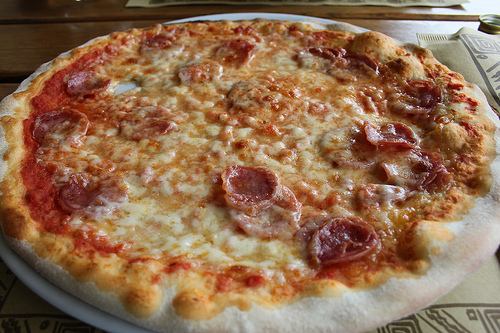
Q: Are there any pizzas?
A: Yes, there is a pizza.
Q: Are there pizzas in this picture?
A: Yes, there is a pizza.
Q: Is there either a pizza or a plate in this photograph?
A: Yes, there is a pizza.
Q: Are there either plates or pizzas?
A: Yes, there is a pizza.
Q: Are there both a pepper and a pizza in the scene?
A: No, there is a pizza but no peppers.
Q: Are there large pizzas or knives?
A: Yes, there is a large pizza.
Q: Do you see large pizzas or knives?
A: Yes, there is a large pizza.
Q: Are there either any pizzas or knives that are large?
A: Yes, the pizza is large.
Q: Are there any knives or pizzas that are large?
A: Yes, the pizza is large.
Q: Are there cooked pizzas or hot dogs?
A: Yes, there is a cooked pizza.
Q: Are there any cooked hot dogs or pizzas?
A: Yes, there is a cooked pizza.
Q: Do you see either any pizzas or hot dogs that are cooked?
A: Yes, the pizza is cooked.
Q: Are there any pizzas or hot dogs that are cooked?
A: Yes, the pizza is cooked.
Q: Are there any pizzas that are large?
A: Yes, there is a large pizza.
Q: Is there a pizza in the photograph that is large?
A: Yes, there is a large pizza.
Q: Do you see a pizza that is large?
A: Yes, there is a pizza that is large.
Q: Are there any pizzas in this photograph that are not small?
A: Yes, there is a large pizza.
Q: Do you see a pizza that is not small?
A: Yes, there is a large pizza.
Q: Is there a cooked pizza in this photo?
A: Yes, there is a cooked pizza.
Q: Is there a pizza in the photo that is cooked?
A: Yes, there is a pizza that is cooked.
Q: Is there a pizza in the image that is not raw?
A: Yes, there is a cooked pizza.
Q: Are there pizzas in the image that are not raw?
A: Yes, there is a cooked pizza.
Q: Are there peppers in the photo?
A: No, there are no peppers.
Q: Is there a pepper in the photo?
A: No, there are no peppers.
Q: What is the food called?
A: The food is a pizza.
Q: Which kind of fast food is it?
A: The food is a pizza.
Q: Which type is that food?
A: This is a pizza.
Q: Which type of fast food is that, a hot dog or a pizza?
A: This is a pizza.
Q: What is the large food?
A: The food is a pizza.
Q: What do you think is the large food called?
A: The food is a pizza.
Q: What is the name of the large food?
A: The food is a pizza.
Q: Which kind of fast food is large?
A: The fast food is a pizza.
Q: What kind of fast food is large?
A: The fast food is a pizza.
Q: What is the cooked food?
A: The food is a pizza.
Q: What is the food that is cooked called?
A: The food is a pizza.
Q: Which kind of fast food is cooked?
A: The fast food is a pizza.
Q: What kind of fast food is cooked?
A: The fast food is a pizza.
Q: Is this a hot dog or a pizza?
A: This is a pizza.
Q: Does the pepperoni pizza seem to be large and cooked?
A: Yes, the pizza is large and cooked.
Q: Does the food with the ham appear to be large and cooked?
A: Yes, the pizza is large and cooked.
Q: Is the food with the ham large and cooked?
A: Yes, the pizza is large and cooked.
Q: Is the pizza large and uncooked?
A: No, the pizza is large but cooked.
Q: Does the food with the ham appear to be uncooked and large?
A: No, the pizza is large but cooked.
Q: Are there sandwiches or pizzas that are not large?
A: No, there is a pizza but it is large.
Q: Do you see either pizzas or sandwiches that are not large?
A: No, there is a pizza but it is large.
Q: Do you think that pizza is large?
A: Yes, the pizza is large.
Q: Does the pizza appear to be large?
A: Yes, the pizza is large.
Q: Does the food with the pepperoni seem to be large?
A: Yes, the pizza is large.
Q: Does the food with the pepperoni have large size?
A: Yes, the pizza is large.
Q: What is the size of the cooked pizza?
A: The pizza is large.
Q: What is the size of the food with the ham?
A: The pizza is large.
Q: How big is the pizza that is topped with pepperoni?
A: The pizza is large.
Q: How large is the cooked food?
A: The pizza is large.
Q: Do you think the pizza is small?
A: No, the pizza is large.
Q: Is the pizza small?
A: No, the pizza is large.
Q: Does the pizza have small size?
A: No, the pizza is large.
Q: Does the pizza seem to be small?
A: No, the pizza is large.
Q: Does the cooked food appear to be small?
A: No, the pizza is large.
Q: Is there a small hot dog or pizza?
A: No, there is a pizza but it is large.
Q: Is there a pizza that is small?
A: No, there is a pizza but it is large.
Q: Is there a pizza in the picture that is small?
A: No, there is a pizza but it is large.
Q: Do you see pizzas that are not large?
A: No, there is a pizza but it is large.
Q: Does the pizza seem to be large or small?
A: The pizza is large.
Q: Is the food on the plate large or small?
A: The pizza is large.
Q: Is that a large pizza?
A: Yes, that is a large pizza.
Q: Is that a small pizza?
A: No, that is a large pizza.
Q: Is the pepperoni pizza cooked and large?
A: Yes, the pizza is cooked and large.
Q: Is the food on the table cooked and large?
A: Yes, the pizza is cooked and large.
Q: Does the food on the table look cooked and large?
A: Yes, the pizza is cooked and large.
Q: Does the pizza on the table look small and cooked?
A: No, the pizza is cooked but large.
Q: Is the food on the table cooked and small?
A: No, the pizza is cooked but large.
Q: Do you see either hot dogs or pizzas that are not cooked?
A: No, there is a pizza but it is cooked.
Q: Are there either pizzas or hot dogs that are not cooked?
A: No, there is a pizza but it is cooked.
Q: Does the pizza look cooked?
A: Yes, the pizza is cooked.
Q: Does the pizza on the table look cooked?
A: Yes, the pizza is cooked.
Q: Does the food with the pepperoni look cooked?
A: Yes, the pizza is cooked.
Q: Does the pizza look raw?
A: No, the pizza is cooked.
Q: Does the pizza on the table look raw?
A: No, the pizza is cooked.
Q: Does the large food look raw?
A: No, the pizza is cooked.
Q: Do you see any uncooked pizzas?
A: No, there is a pizza but it is cooked.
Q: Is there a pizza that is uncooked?
A: No, there is a pizza but it is cooked.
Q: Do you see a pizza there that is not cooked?
A: No, there is a pizza but it is cooked.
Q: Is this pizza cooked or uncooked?
A: The pizza is cooked.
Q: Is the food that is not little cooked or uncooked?
A: The pizza is cooked.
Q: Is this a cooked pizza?
A: Yes, this is a cooked pizza.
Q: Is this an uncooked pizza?
A: No, this is a cooked pizza.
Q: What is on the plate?
A: The pizza is on the plate.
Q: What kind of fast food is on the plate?
A: The food is a pizza.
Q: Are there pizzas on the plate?
A: Yes, there is a pizza on the plate.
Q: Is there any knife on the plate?
A: No, there is a pizza on the plate.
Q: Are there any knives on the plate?
A: No, there is a pizza on the plate.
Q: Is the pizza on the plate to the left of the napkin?
A: Yes, the pizza is on the plate.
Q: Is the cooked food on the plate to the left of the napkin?
A: Yes, the pizza is on the plate.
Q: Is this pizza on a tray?
A: No, the pizza is on the plate.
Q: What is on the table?
A: The pizza is on the table.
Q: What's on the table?
A: The pizza is on the table.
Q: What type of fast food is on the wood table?
A: The food is a pizza.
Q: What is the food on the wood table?
A: The food is a pizza.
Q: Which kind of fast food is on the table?
A: The food is a pizza.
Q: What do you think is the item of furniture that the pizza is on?
A: The piece of furniture is a table.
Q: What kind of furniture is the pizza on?
A: The pizza is on the table.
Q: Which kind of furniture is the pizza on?
A: The pizza is on the table.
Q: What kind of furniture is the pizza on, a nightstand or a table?
A: The pizza is on a table.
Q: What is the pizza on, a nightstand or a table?
A: The pizza is on a table.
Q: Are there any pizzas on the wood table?
A: Yes, there is a pizza on the table.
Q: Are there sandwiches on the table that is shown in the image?
A: No, there is a pizza on the table.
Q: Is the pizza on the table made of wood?
A: Yes, the pizza is on the table.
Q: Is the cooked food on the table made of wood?
A: Yes, the pizza is on the table.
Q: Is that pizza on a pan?
A: No, the pizza is on the table.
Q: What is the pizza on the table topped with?
A: The pizza is topped with pepperoni.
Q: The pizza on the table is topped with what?
A: The pizza is topped with pepperoni.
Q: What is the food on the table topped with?
A: The pizza is topped with pepperoni.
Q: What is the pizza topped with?
A: The pizza is topped with pepperoni.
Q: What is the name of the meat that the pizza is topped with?
A: The meat is pepperoni.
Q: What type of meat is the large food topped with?
A: The pizza is topped with pepperoni.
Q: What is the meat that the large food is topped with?
A: The meat is pepperoni.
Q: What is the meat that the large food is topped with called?
A: The meat is pepperoni.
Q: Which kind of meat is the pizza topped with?
A: The pizza is topped with pepperoni.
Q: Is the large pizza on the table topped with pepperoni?
A: Yes, the pizza is topped with pepperoni.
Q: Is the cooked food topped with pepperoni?
A: Yes, the pizza is topped with pepperoni.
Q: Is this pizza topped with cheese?
A: No, the pizza is topped with pepperoni.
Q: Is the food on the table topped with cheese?
A: No, the pizza is topped with pepperoni.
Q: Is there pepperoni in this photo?
A: Yes, there is pepperoni.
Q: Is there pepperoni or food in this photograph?
A: Yes, there is pepperoni.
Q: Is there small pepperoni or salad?
A: Yes, there is small pepperoni.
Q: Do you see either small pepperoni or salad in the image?
A: Yes, there is small pepperoni.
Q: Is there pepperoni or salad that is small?
A: Yes, the pepperoni is small.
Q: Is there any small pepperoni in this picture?
A: Yes, there is small pepperoni.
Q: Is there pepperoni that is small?
A: Yes, there is pepperoni that is small.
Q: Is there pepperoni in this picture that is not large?
A: Yes, there is small pepperoni.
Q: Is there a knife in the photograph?
A: No, there are no knives.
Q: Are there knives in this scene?
A: No, there are no knives.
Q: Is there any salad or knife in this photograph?
A: No, there are no knives or salad.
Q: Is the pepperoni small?
A: Yes, the pepperoni is small.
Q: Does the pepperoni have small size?
A: Yes, the pepperoni is small.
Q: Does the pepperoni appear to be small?
A: Yes, the pepperoni is small.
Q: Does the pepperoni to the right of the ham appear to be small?
A: Yes, the pepperoni is small.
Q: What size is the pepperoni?
A: The pepperoni is small.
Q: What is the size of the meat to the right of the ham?
A: The pepperoni is small.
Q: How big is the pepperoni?
A: The pepperoni is small.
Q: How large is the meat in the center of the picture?
A: The pepperoni is small.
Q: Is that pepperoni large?
A: No, the pepperoni is small.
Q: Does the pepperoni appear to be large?
A: No, the pepperoni is small.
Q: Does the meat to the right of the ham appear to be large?
A: No, the pepperoni is small.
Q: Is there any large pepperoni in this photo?
A: No, there is pepperoni but it is small.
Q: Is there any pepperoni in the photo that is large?
A: No, there is pepperoni but it is small.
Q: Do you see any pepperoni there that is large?
A: No, there is pepperoni but it is small.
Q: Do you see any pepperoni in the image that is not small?
A: No, there is pepperoni but it is small.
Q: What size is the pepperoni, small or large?
A: The pepperoni is small.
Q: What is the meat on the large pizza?
A: The meat is pepperoni.